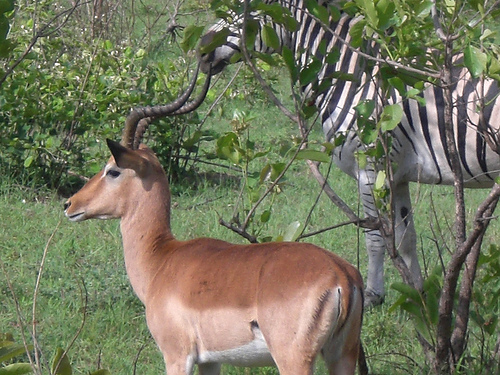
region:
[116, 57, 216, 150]
the horns on top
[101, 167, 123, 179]
the eyes are open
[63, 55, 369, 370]
a reindeer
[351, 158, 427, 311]
the front legs of zebra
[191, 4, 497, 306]
a zebra standing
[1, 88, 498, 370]
the green grass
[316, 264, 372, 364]
back of deer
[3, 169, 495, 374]
branches upfront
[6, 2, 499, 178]
the bushes in back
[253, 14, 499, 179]
the stripes on coat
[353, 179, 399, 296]
leg of a zebra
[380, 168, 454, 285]
leg of a zebra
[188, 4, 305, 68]
head of a zebra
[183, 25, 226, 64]
nose of a zebra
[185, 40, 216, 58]
a nose of a zebra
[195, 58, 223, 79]
mouth of a zebra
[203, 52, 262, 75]
a mouth of a zebra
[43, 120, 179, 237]
head of a deer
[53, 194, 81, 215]
nose of a deer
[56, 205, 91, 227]
mouth of a deer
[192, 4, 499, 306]
a zebra standing behind the tree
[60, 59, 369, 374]
the gazelle standing in front of the tree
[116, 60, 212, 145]
the horns on the top of the gazelle's head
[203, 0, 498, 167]
the branch with many green leaves on it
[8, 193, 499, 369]
lots of green grass on the ground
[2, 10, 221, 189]
a bush with some green leaves on them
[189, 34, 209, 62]
the zebra nose on the end of the snout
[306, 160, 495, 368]
the tree branches by the zebra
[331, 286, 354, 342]
the tale of the gazelle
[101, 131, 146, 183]
the big ear of the gazelle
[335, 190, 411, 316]
leg of a zebra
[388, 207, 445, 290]
leg of a zebra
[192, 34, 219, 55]
nose of a zebra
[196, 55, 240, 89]
mouth of a zebra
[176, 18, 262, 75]
jaw of a zebra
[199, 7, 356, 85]
head of a zebra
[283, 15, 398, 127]
neck of a zebra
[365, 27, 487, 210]
body of a zebra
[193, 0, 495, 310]
zebra standing on the grass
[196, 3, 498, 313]
black and white stripes on the body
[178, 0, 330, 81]
face is partially hidden by leaves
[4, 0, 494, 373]
green grass on the ground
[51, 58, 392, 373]
animal with long horns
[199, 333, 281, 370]
underbelly is white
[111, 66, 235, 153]
two long horns on top of the head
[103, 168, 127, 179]
eye on the side of the head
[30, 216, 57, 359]
thin branch with no leaves on it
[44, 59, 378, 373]
animal standing in the grass